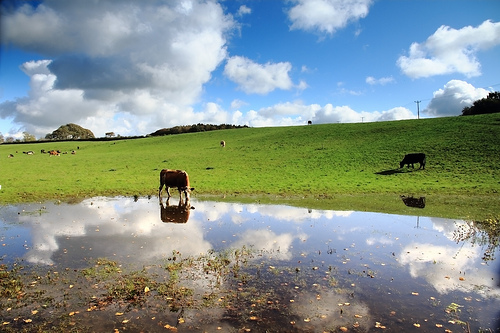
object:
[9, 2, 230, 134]
clouds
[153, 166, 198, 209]
cow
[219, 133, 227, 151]
cow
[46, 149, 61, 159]
cow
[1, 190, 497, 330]
puddle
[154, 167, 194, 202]
cow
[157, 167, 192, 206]
cow's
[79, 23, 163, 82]
clouds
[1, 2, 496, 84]
sky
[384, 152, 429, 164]
cows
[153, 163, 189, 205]
cows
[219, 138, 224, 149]
cows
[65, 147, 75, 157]
cows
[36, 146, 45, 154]
cows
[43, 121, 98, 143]
tree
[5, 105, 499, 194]
hill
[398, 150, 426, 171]
cow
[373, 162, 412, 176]
shadow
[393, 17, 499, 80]
cloud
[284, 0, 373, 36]
cloud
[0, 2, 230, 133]
cloud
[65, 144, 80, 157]
cow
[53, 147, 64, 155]
cow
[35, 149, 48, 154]
cow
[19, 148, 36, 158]
cow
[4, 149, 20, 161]
cow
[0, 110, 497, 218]
field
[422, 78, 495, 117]
cloud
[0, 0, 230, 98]
cloud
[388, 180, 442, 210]
cow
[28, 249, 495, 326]
leaves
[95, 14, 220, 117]
clouds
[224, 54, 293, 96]
clouds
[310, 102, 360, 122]
clouds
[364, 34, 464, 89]
clouds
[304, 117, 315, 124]
cow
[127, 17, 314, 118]
clouds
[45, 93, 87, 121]
clouds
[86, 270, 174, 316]
dirt leaves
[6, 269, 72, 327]
dirt leaves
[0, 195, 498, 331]
water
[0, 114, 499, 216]
grass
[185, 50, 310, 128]
clouds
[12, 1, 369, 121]
clouds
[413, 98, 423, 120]
electricity post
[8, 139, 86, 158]
cows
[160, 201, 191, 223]
reflection